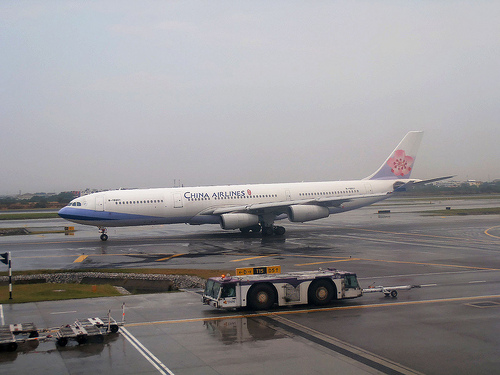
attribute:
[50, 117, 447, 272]
airlines — china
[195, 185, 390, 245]
wing — one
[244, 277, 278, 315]
wheel — large 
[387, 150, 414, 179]
flower — pink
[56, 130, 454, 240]
plane — long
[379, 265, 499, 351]
mark lines — yellow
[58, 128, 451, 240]
jet — passenger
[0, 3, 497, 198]
sky — grey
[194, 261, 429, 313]
truck — long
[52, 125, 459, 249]
jet — blue, white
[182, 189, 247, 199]
writing — blue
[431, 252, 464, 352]
ground — asphalt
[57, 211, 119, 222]
line — blue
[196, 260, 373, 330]
ground support — airport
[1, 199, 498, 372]
runway — tarmac